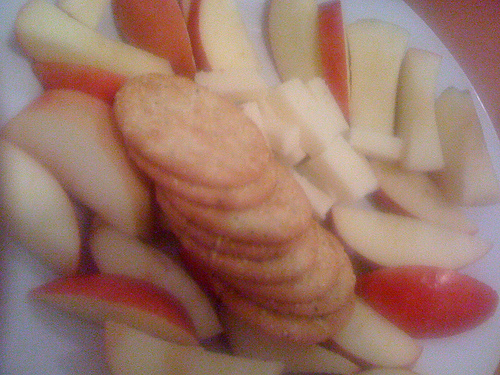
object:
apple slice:
[427, 85, 494, 206]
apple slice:
[393, 49, 446, 172]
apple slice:
[344, 18, 407, 137]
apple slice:
[317, 0, 352, 125]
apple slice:
[267, 0, 325, 81]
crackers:
[113, 70, 358, 345]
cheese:
[193, 68, 262, 102]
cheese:
[265, 76, 341, 157]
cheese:
[313, 146, 379, 202]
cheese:
[346, 124, 405, 165]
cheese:
[264, 123, 302, 153]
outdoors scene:
[165, 75, 367, 267]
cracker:
[115, 76, 266, 185]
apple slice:
[30, 270, 206, 346]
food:
[0, 0, 498, 374]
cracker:
[227, 223, 351, 313]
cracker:
[132, 142, 277, 214]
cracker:
[165, 161, 311, 241]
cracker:
[169, 224, 320, 283]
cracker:
[223, 244, 346, 300]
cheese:
[309, 77, 348, 132]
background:
[0, 0, 500, 375]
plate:
[0, 4, 500, 375]